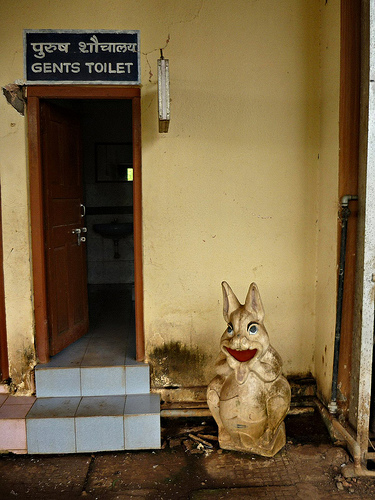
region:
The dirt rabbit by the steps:
[220, 290, 285, 455]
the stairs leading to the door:
[12, 358, 157, 449]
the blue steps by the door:
[41, 362, 158, 449]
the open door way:
[28, 91, 139, 366]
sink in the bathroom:
[92, 208, 131, 243]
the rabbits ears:
[215, 278, 265, 319]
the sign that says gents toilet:
[27, 33, 139, 84]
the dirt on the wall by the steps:
[11, 350, 207, 396]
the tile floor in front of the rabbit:
[193, 457, 326, 495]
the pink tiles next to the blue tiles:
[6, 389, 30, 451]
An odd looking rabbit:
[184, 271, 316, 468]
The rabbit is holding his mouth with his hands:
[219, 335, 262, 373]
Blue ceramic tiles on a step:
[43, 358, 158, 449]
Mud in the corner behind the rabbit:
[298, 393, 334, 452]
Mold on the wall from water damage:
[143, 332, 211, 389]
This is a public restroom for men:
[29, 35, 156, 373]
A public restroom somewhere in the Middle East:
[25, 28, 145, 86]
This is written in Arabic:
[25, 32, 136, 55]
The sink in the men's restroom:
[90, 211, 125, 257]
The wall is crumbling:
[0, 81, 20, 127]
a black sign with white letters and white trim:
[18, 27, 146, 86]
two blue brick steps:
[34, 361, 159, 451]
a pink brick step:
[0, 390, 25, 455]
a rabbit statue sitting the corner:
[202, 277, 293, 455]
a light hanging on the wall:
[154, 48, 175, 134]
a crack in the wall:
[140, 49, 158, 89]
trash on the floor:
[170, 419, 215, 459]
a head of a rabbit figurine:
[212, 278, 270, 367]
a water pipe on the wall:
[326, 194, 361, 418]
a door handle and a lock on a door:
[73, 198, 92, 251]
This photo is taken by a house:
[5, 34, 311, 411]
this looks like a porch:
[43, 333, 251, 458]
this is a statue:
[205, 273, 363, 461]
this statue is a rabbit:
[189, 286, 327, 461]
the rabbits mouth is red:
[213, 339, 271, 361]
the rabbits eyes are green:
[213, 308, 282, 346]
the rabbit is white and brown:
[193, 273, 321, 483]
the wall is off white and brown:
[150, 161, 308, 305]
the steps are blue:
[30, 382, 128, 472]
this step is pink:
[4, 392, 31, 445]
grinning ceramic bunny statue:
[206, 276, 292, 459]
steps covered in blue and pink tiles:
[0, 356, 165, 448]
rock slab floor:
[0, 420, 361, 496]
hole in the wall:
[2, 83, 28, 113]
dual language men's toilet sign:
[23, 27, 137, 81]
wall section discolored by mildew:
[150, 337, 331, 410]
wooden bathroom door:
[20, 81, 88, 356]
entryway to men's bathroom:
[0, 25, 166, 445]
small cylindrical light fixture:
[151, 45, 174, 135]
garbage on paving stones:
[161, 416, 218, 450]